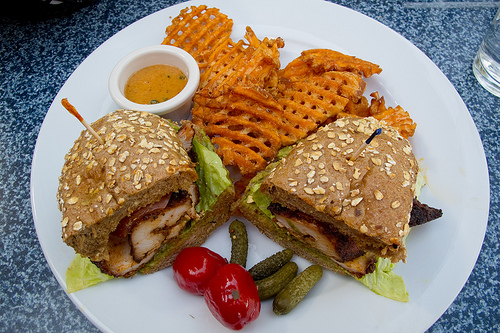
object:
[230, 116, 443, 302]
burger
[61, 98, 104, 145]
toothpick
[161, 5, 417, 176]
fries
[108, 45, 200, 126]
sauce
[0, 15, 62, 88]
table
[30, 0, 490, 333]
plate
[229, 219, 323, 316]
pickles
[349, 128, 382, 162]
toothpick